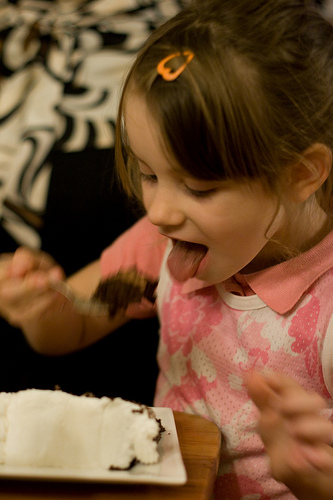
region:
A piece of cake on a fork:
[29, 256, 165, 326]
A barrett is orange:
[153, 43, 196, 85]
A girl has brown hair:
[108, 2, 331, 289]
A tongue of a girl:
[160, 233, 212, 284]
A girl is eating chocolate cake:
[0, 1, 330, 362]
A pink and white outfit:
[97, 212, 331, 497]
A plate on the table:
[2, 385, 225, 498]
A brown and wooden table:
[1, 410, 223, 498]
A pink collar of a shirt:
[177, 229, 331, 317]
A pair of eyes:
[132, 156, 223, 206]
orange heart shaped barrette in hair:
[151, 42, 198, 84]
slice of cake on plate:
[1, 374, 190, 487]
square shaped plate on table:
[2, 387, 194, 489]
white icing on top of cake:
[1, 384, 161, 473]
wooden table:
[2, 389, 226, 497]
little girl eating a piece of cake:
[3, 2, 332, 497]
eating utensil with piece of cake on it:
[21, 249, 161, 327]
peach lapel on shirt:
[242, 229, 331, 330]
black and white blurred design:
[0, 1, 190, 251]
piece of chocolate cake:
[150, 406, 173, 445]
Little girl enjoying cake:
[1, 17, 329, 495]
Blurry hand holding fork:
[0, 246, 117, 322]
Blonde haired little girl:
[119, 15, 330, 284]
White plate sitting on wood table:
[0, 388, 223, 495]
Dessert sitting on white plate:
[0, 387, 188, 484]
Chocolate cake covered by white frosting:
[0, 385, 163, 469]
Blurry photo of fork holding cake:
[41, 257, 159, 320]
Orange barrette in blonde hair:
[155, 49, 193, 80]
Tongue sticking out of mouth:
[160, 242, 202, 281]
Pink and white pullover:
[106, 224, 332, 490]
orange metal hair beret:
[152, 49, 198, 84]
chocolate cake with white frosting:
[1, 384, 169, 477]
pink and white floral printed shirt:
[98, 212, 332, 498]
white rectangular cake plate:
[0, 402, 189, 484]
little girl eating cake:
[0, 2, 332, 497]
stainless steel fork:
[41, 265, 108, 317]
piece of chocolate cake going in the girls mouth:
[84, 257, 161, 323]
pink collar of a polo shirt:
[176, 233, 332, 316]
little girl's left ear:
[282, 141, 330, 202]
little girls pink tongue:
[151, 234, 211, 286]